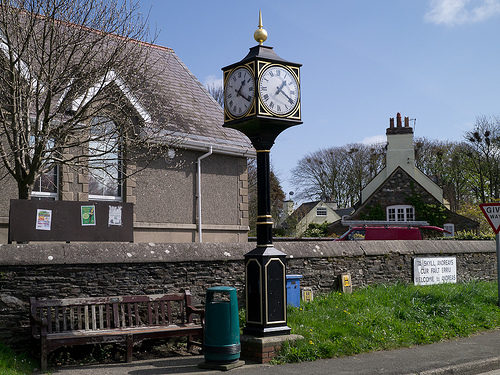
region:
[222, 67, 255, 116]
A clock face on a box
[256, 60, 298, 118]
A clock face on a box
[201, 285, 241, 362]
A green trash can near a bench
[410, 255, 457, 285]
A white sign with black letters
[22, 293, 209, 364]
A brown bench on a sidewalk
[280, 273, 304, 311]
A blue box in some grass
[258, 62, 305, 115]
a clock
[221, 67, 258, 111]
a clock on the side of the pole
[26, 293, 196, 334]
a bench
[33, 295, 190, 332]
the bench is brown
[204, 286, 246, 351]
a trash can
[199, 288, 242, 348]
a green trash can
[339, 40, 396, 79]
the sky is clear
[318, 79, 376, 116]
the clear blue sky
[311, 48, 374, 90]
a clear sky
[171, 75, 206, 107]
the roof on the house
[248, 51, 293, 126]
black and white clock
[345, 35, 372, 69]
white clouds in blue sky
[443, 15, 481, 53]
white clouds in blue sky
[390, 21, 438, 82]
white clouds in blue sky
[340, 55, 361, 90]
white clouds in blue sky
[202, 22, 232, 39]
white clouds in blue sky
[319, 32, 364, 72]
white clouds in blue sky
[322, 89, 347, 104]
white clouds in blue sky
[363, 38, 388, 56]
white clouds in blue sky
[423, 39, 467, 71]
white clouds in blue sky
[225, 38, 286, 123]
white clock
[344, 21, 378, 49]
white clouds in blue sky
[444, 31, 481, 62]
white clouds in blue sky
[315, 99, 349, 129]
white clouds in blue sky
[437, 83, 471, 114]
white clouds in blue sky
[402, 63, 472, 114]
white clouds in blue sky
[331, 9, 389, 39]
white clouds in blue sky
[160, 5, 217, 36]
white clouds in blue sky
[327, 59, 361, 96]
white clouds in blue sky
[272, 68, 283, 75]
roman numeral on clock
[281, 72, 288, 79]
roman numeral on clock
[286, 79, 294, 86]
roman numeral on clock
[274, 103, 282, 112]
roman numeral on clock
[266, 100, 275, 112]
roman numeral on clock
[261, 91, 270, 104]
roman numeral on clock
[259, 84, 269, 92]
roman numeral on clock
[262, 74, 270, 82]
roman numeral on clock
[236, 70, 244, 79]
roman numeral on clock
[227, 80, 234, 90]
roman numeral on clock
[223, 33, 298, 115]
black and white clock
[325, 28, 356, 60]
white clouds in blue sky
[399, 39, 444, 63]
white clouds in blue sky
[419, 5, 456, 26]
white clouds in blue sky